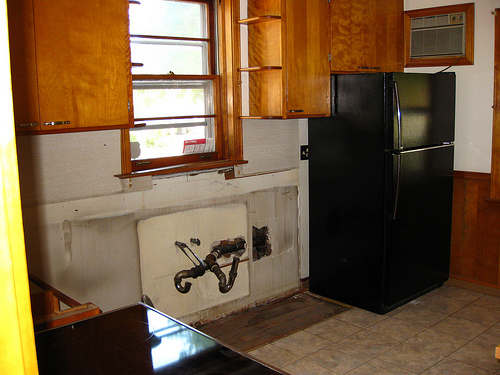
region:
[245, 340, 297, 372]
a tile on the floor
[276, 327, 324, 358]
a tile on the floor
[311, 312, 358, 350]
a tile on the floor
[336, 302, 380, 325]
a tile on the floor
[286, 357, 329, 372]
a tile on the floor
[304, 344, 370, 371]
a tile on the floor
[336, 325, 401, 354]
a tile on the floor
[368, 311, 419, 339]
a tile on the floor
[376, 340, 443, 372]
a tile on the floor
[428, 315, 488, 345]
a tile on the floor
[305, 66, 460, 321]
The black refrigerator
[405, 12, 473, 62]
The a.c. unit on the wall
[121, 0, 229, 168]
The window in the kitchen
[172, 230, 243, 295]
The exposed pipes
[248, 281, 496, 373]
The tile on the ground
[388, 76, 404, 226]
The handles of the refrigerator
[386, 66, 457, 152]
The freezer on top of the fridge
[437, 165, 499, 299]
The wood paneling on the wall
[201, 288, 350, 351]
The patch of ground with no tiles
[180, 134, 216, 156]
The white and red sign on the window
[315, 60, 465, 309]
a black fridge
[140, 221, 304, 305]
plumbing pipes for a sink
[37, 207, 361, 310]
a tore up wall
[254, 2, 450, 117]
brown cabinets above the fridge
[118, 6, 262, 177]
a window framed in brown trimming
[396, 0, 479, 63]
an ac unit framed in brown trimming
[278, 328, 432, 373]
a tiled floor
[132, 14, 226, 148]
a window that shows daylight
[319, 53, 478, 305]
a fridge with the freezer on top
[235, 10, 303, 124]
shelves on the side of the cabinets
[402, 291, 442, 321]
small white spot on floor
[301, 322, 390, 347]
brown tiles on floor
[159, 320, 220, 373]
reflection on black counter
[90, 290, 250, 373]
large black counter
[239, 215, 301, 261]
small black spot on wall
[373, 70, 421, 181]
silver handle on black fridge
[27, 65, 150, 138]
large brown cabinet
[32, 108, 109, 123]
large silver bracket on cabinet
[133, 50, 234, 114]
large brown frame on window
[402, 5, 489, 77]
tan air conditioner in kitchen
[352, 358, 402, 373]
a tile on the floor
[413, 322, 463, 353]
a tile on the floor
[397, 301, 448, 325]
a tile on the floor